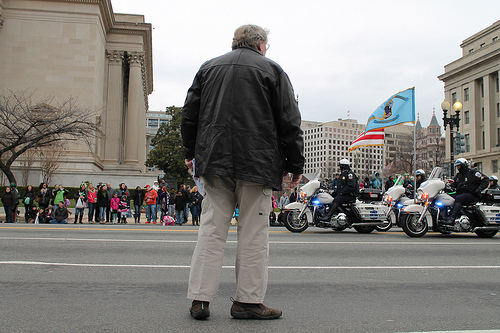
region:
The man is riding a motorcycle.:
[282, 143, 399, 245]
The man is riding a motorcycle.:
[398, 158, 498, 243]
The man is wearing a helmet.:
[281, 152, 396, 242]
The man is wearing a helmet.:
[396, 157, 429, 204]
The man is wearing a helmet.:
[402, 155, 498, 241]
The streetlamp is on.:
[448, 92, 468, 132]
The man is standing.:
[166, 8, 309, 326]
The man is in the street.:
[171, 18, 332, 330]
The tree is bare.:
[1, 83, 108, 228]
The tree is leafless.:
[0, 78, 110, 229]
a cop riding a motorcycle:
[280, 154, 397, 236]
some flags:
[344, 88, 431, 158]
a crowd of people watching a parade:
[14, 163, 207, 244]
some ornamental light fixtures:
[432, 93, 472, 138]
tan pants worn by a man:
[181, 164, 283, 305]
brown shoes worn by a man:
[187, 293, 287, 325]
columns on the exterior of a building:
[88, 41, 164, 180]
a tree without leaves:
[11, 100, 100, 179]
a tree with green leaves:
[142, 102, 200, 177]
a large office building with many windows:
[304, 116, 389, 189]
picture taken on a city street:
[27, 20, 477, 312]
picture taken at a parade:
[0, 27, 487, 305]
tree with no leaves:
[4, 93, 99, 204]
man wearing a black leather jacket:
[153, 54, 313, 310]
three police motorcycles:
[287, 154, 495, 237]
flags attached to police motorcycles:
[345, 87, 430, 201]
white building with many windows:
[295, 113, 397, 180]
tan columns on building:
[102, 55, 154, 170]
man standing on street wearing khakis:
[170, 13, 308, 324]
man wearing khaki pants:
[184, 182, 276, 304]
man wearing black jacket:
[175, 49, 308, 189]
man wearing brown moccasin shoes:
[185, 300, 290, 321]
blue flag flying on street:
[362, 84, 425, 225]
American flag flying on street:
[347, 126, 392, 202]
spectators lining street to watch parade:
[6, 173, 303, 223]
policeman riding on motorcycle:
[281, 153, 393, 240]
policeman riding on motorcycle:
[403, 152, 498, 237]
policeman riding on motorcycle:
[372, 165, 436, 232]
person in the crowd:
[73, 186, 87, 221]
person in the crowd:
[96, 182, 111, 217]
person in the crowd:
[107, 192, 124, 224]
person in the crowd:
[130, 183, 145, 234]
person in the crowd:
[144, 186, 163, 222]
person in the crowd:
[153, 178, 175, 225]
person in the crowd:
[172, 188, 189, 222]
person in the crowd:
[55, 201, 75, 226]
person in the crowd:
[43, 207, 59, 227]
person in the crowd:
[30, 204, 42, 222]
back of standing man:
[176, 23, 307, 318]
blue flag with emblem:
[365, 85, 416, 191]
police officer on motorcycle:
[284, 158, 389, 232]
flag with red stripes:
[349, 128, 386, 150]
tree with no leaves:
[1, 91, 101, 182]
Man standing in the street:
[202, 13, 334, 270]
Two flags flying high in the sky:
[322, 61, 437, 168]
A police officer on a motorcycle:
[289, 154, 388, 245]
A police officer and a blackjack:
[431, 165, 484, 215]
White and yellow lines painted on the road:
[57, 221, 118, 293]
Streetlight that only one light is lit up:
[433, 81, 466, 168]